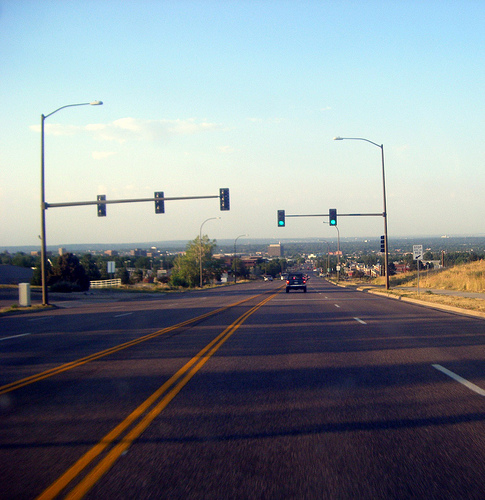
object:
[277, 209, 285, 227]
streetlight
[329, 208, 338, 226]
streetlight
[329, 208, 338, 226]
street light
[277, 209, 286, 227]
street light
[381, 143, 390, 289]
pole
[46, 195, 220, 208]
pole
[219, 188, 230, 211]
light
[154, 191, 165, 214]
light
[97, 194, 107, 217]
light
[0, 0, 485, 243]
sky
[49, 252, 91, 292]
bush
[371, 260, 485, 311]
grass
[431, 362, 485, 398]
stripes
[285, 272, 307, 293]
suv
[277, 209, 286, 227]
light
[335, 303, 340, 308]
stripes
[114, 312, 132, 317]
stripes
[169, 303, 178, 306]
stripes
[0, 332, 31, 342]
stripes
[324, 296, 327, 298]
stripes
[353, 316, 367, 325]
zebras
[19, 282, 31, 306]
white object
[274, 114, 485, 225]
clouds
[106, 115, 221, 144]
clouds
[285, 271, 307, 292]
car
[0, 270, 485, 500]
road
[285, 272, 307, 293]
vehicle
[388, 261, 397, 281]
trees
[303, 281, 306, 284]
light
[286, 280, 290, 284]
light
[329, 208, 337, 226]
light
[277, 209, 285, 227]
light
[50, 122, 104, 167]
clouds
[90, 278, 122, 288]
fence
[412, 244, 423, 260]
street sign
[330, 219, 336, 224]
signal light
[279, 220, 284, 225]
signal light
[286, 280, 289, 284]
taillight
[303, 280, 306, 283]
taillight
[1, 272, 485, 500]
street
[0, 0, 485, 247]
sky